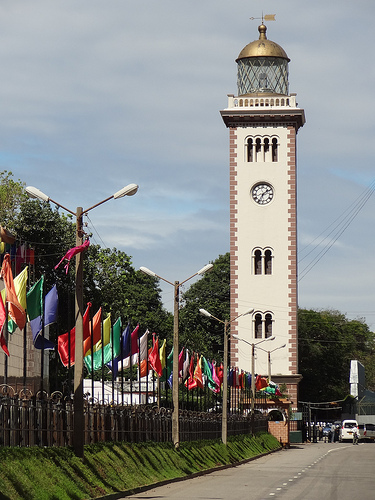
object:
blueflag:
[31, 285, 57, 350]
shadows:
[2, 429, 375, 499]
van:
[338, 419, 361, 441]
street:
[212, 423, 372, 497]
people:
[333, 426, 339, 442]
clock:
[245, 177, 277, 211]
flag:
[107, 311, 150, 349]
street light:
[74, 181, 140, 454]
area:
[0, 0, 375, 497]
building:
[210, 4, 319, 458]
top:
[228, 9, 292, 107]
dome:
[234, 24, 290, 65]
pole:
[171, 280, 179, 449]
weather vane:
[249, 14, 276, 21]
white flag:
[105, 328, 150, 374]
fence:
[0, 242, 283, 498]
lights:
[101, 182, 139, 200]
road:
[104, 437, 375, 497]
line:
[275, 485, 281, 491]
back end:
[341, 419, 360, 440]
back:
[339, 419, 358, 439]